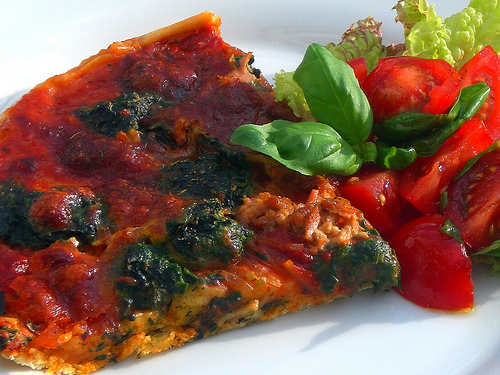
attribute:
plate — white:
[229, 290, 437, 375]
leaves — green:
[258, 82, 442, 211]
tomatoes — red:
[338, 104, 496, 317]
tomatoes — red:
[378, 173, 458, 277]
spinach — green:
[136, 85, 372, 317]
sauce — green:
[189, 177, 403, 328]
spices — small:
[76, 125, 348, 362]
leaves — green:
[263, 63, 424, 250]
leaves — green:
[246, 51, 403, 209]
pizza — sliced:
[34, 25, 352, 344]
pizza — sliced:
[42, 52, 401, 348]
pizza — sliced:
[34, 17, 350, 373]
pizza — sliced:
[78, 44, 368, 303]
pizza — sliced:
[55, 35, 378, 355]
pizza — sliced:
[20, 19, 330, 368]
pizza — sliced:
[59, 51, 366, 372]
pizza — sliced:
[47, 35, 327, 286]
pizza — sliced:
[37, 36, 365, 363]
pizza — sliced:
[20, 0, 300, 360]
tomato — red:
[377, 166, 457, 316]